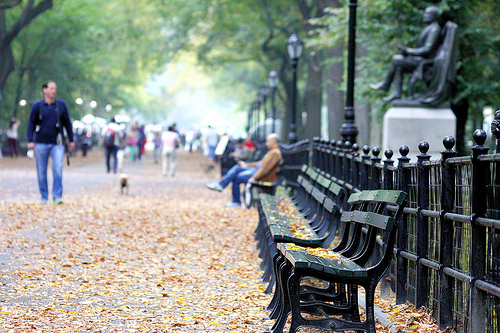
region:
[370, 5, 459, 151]
Statue of a man in the park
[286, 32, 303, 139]
Lamp and post located in park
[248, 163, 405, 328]
Benches in the park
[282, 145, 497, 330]
Fence in the park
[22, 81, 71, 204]
Man walking in the park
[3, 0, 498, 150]
Trees creating a canopy in the park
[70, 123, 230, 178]
People walking in the park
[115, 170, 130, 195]
dog walking away from camera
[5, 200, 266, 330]
Leaves on the ground on walkway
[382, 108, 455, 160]
Pedestal for statue in the park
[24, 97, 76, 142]
A blue sweater.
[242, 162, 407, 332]
A row of benches.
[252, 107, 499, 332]
A black metal fence.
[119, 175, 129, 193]
A small dog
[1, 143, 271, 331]
Yellow leaveas on the ground.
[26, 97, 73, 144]
A dark blue sweater.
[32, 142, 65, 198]
Light colored blue jeans.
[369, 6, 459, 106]
A statue of a man sitting.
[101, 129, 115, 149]
A grey and red backpack.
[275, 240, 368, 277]
Seat of a bench.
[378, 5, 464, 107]
bronze statue is blurry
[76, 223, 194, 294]
brown leaves lying on sidewalk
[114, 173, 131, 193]
photo of dog is blurry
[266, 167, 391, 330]
wood and iron benches lining fence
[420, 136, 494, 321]
black iron fencing along sidewalk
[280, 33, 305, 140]
light pole is blurry in distance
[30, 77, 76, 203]
man walking on sidewalk in park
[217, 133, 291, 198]
person sitting on bench is blurry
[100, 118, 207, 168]
several people walking in the park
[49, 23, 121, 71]
green trees in distance are blurry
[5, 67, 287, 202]
People walking on a walkway.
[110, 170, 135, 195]
There is a dog standing on the walkway.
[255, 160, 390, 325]
A line of benches along the side of the walkway.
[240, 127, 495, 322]
There is a black metal fence.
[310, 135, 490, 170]
There are balls on the top of the fence posts.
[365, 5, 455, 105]
A black statue of a man sitting on a chair.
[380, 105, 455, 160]
There is a white base beneath the statue.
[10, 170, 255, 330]
There are leaves on the ground.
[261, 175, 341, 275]
There are leaves on the benches.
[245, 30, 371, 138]
Black lamp posts along the walkway.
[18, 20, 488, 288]
a scene at a park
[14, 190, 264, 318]
a lot of leaves on the ground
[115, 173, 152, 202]
a dog in the photo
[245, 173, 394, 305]
benches for sitting down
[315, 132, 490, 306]
a black gate in the background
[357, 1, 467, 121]
a statue in the playground area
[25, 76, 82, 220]
a man is walking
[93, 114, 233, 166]
lots of people in the background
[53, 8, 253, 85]
lots of leaves on the trees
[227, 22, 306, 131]
lights in the area